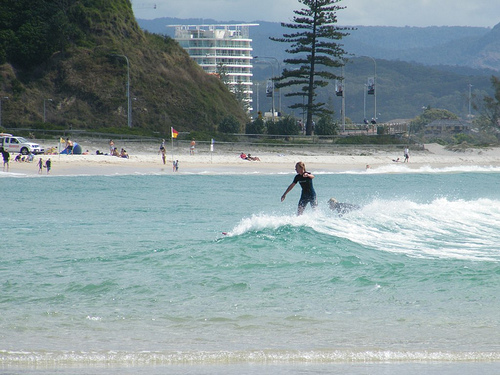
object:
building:
[335, 118, 472, 139]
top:
[293, 172, 316, 196]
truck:
[0, 133, 44, 155]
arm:
[308, 174, 315, 179]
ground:
[330, 146, 359, 171]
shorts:
[67, 146, 74, 150]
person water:
[263, 156, 322, 229]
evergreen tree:
[266, 0, 356, 135]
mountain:
[136, 17, 500, 71]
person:
[24, 152, 34, 162]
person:
[82, 150, 90, 155]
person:
[14, 154, 21, 163]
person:
[403, 146, 409, 164]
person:
[172, 161, 175, 172]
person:
[175, 159, 179, 172]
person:
[37, 158, 46, 174]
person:
[46, 158, 52, 175]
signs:
[367, 77, 374, 95]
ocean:
[6, 168, 497, 350]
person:
[0, 149, 10, 171]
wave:
[0, 165, 500, 375]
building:
[169, 21, 261, 125]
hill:
[1, 1, 249, 135]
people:
[122, 150, 130, 159]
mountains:
[244, 54, 500, 138]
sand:
[7, 144, 494, 172]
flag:
[172, 129, 179, 139]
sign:
[210, 144, 213, 152]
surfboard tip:
[222, 232, 228, 236]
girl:
[280, 162, 318, 217]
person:
[366, 165, 371, 170]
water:
[2, 171, 489, 368]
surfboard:
[222, 232, 231, 237]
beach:
[11, 132, 484, 175]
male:
[189, 138, 195, 156]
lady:
[158, 144, 167, 164]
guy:
[327, 198, 361, 219]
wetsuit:
[293, 172, 317, 208]